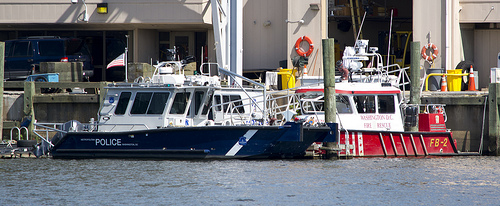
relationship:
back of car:
[73, 77, 95, 94] [61, 54, 96, 81]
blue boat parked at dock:
[49, 38, 340, 160] [13, 79, 101, 117]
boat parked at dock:
[284, 37, 459, 156] [13, 79, 101, 117]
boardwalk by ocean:
[177, 91, 442, 152] [83, 157, 474, 202]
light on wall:
[96, 3, 110, 20] [10, 2, 226, 28]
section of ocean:
[196, 167, 409, 202] [0, 156, 497, 204]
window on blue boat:
[114, 90, 129, 115] [49, 38, 340, 160]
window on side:
[114, 90, 129, 115] [51, 85, 311, 169]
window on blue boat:
[129, 89, 168, 119] [49, 38, 340, 160]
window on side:
[129, 89, 168, 119] [51, 85, 311, 169]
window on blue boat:
[170, 90, 189, 115] [49, 38, 340, 160]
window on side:
[170, 90, 189, 115] [51, 85, 311, 169]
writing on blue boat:
[90, 134, 124, 148] [49, 38, 340, 160]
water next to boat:
[0, 155, 498, 204] [30, 34, 330, 163]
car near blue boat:
[28, 42, 80, 99] [49, 38, 340, 160]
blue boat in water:
[49, 38, 340, 160] [9, 157, 481, 198]